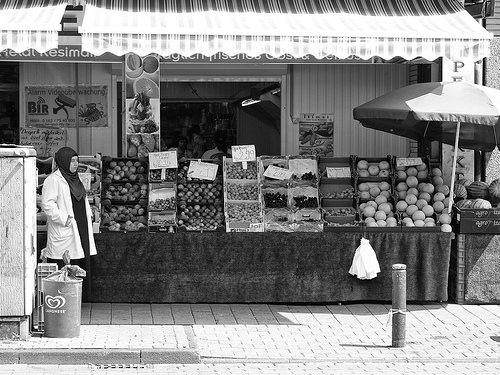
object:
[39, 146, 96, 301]
lady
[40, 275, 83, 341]
trash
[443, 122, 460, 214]
pole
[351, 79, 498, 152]
umbrella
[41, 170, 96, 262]
coat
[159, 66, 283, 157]
window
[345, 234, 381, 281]
bags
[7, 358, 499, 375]
road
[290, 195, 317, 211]
fruit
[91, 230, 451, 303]
shelf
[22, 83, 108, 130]
sign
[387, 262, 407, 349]
post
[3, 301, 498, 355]
sidewalk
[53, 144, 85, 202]
scarf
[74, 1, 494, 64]
awning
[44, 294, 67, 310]
heart